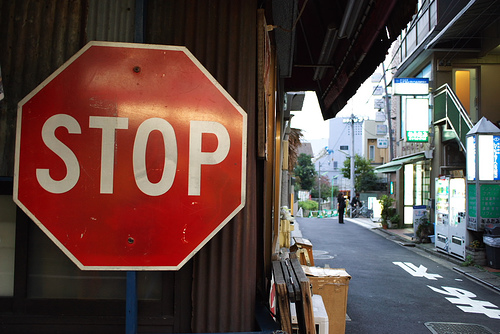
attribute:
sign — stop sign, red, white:
[11, 39, 250, 277]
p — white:
[183, 119, 232, 197]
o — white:
[131, 114, 179, 200]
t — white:
[86, 115, 130, 195]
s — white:
[34, 113, 82, 197]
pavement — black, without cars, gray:
[286, 214, 499, 334]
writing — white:
[391, 257, 499, 320]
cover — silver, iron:
[421, 319, 491, 333]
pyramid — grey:
[464, 114, 498, 135]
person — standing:
[336, 189, 350, 226]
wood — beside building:
[271, 250, 314, 334]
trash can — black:
[483, 220, 499, 268]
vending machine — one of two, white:
[431, 173, 454, 259]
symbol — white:
[391, 258, 445, 283]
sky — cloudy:
[287, 76, 372, 140]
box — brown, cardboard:
[306, 264, 352, 334]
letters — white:
[34, 113, 232, 199]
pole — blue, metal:
[124, 269, 139, 334]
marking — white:
[426, 281, 500, 321]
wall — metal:
[0, 1, 262, 334]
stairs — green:
[432, 92, 471, 152]